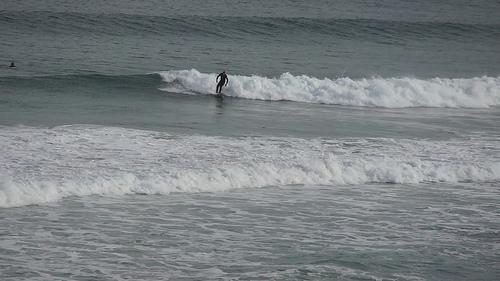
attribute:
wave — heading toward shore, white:
[34, 69, 490, 123]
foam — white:
[168, 68, 498, 111]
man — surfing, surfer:
[212, 66, 233, 93]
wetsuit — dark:
[215, 74, 230, 92]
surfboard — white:
[212, 87, 228, 98]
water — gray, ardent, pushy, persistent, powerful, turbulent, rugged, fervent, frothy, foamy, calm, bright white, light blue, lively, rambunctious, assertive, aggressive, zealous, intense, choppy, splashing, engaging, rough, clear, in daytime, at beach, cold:
[2, 3, 499, 280]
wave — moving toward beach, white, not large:
[2, 120, 499, 212]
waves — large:
[3, 10, 495, 121]